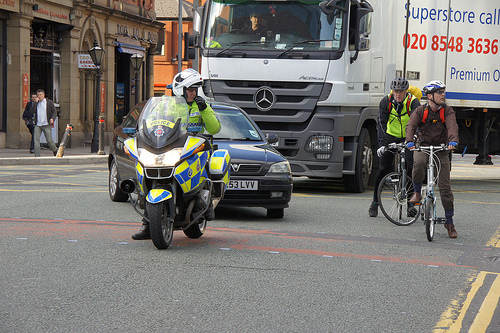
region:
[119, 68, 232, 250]
person on a motorcycle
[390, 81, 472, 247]
person on a bike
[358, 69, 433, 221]
person on a bike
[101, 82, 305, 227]
car on the street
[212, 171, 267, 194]
license plate on a car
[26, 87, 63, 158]
person walking on the sidewalk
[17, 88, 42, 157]
person walking on the sidewalk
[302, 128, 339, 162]
headlight on a truck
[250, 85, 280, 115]
emblem on a truck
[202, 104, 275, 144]
windshield on a car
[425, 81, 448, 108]
Man wearing a blue and white helmet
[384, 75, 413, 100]
Man wearing a black helmet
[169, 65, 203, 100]
Man wearing a white helmet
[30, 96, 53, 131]
Man wearing white shirt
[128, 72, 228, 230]
Police officer on motorcycle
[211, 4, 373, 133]
White box truck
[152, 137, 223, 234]
Blue and Yellow Motorcycle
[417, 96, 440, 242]
Man riding bike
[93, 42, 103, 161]
Black and glass light pole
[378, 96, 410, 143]
Man wearing yellow and black jacket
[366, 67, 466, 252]
two men on bicycles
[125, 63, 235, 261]
police on a yellow and blue checkered motorcycle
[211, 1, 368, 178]
man visible in semi front window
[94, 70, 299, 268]
motorcycle in front of a car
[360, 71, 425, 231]
bicyclist wearing gray helmet and yellow vest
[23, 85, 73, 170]
people walking on a sidewalk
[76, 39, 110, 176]
street lamp on street corner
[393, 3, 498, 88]
painted lettering on side of trailer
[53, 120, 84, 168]
safety bumper pole on street corner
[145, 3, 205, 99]
orange painted building in background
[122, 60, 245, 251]
A MAN RIDING A MOTORCYCLE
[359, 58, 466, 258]
TWO MEN ON BIKES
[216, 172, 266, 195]
A LICENSE PLATE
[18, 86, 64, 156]
TWO MEN WALKING ON THE SIDEWALK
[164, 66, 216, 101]
A WHITE HELMET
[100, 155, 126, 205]
REAR CAR TIRE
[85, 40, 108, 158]
A STREET LAMP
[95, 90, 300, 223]
A BLACK CAR ON THE STREET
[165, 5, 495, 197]
A LARGE WHITE TRUCK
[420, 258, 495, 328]
MARKINGS ON THE PAVEMENT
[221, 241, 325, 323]
the ground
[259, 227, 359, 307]
the ground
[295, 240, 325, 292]
the ground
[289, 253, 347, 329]
the ground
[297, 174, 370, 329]
the ground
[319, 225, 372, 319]
the ground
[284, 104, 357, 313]
the ground